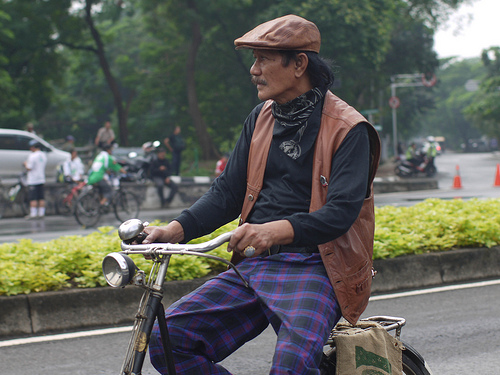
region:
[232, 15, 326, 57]
The brown leather hat on the man's head.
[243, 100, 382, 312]
The brown leather vest the man is wearing.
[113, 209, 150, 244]
The silver bell on the bicycle handle bars.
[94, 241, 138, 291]
The light on the front of the bicycle.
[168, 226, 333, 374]
The plaid pants the man is wearing.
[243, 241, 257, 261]
The ring on the man's finger.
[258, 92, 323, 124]
The black and gray colored scarf around the man's neck.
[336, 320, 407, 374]
The brown burlap bag hanging on the back of the bicycle.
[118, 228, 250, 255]
The handle bars of the bicycle.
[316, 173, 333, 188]
The pin on the right side of the man's brown leather vest.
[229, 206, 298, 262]
Man holding bike handle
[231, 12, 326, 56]
Man's brown hat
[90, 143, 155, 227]
boy riding bike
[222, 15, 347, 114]
Face of man riding bike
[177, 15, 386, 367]
Man riding a bike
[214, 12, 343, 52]
The brown hat of man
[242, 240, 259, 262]
Ring worn by man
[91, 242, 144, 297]
Headlight on bike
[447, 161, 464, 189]
Orange colored cone in street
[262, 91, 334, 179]
scarf worn by man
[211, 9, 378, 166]
man wears a cap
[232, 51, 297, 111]
man has a mustache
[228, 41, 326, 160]
man wears a bandanna around his neck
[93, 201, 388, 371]
man is riding a bicycle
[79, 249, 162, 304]
bicycle has a headlight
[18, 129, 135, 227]
another person rides a bicycle too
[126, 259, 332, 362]
man wears purple plaid pants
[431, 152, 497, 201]
traffic cones in the street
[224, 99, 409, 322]
man wears a brown leather vest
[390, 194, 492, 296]
median strip has light green plants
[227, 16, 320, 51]
The man is wearing a hat.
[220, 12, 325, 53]
The man is wearing a brown hat.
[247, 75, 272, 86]
The man has a moustache.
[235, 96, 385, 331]
The man has a jacket.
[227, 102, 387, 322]
The man has a brown jacket.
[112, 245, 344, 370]
The man is wearing pants.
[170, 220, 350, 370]
His pants are multicolored.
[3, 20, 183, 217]
A group of people is in the background.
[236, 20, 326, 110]
The man is looking away from the camera.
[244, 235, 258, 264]
The man has a ring.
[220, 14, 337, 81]
The man has a hat on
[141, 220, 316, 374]
The man has on plaid pants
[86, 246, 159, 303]
The bike has a light on it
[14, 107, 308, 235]
There is a person on a bike in the back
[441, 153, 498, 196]
Cones are in the back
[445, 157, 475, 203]
The cone is orange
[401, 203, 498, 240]
The bush is green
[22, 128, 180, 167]
The kids have on helmets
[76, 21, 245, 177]
The trees are tall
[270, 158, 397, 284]
The man has a black shirt on